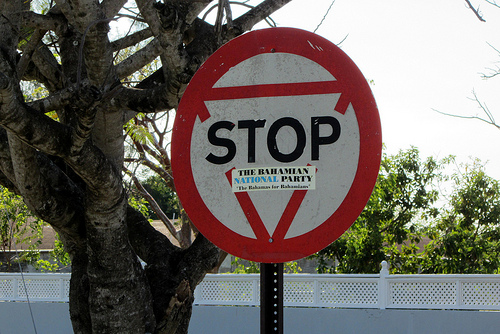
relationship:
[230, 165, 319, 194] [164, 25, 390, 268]
sticker across sign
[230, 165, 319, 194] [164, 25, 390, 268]
sticker stuck on sign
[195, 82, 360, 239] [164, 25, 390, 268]
triangle across sign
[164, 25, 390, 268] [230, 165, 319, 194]
sign with sticker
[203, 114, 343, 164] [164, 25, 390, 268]
letters across sign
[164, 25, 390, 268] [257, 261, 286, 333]
sign attached to post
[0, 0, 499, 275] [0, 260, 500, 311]
trees behind fence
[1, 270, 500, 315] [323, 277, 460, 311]
fence has holes